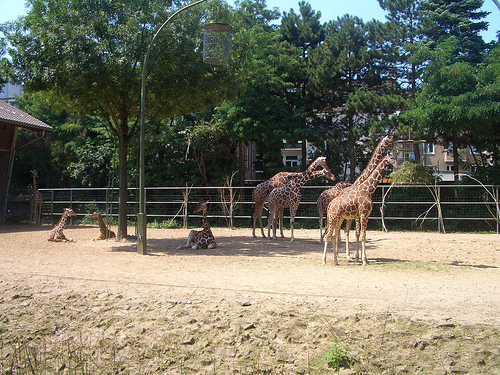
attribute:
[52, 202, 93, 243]
giraffe — baby, tall, on, full, sitting, standing, shed, face, captivity, four, lying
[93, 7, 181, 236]
tree — long, tall, group, beautiful, background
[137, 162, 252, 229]
fence — white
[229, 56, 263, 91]
leaf — green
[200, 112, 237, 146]
plant — green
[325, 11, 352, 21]
sun — shine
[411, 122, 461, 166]
building — behind